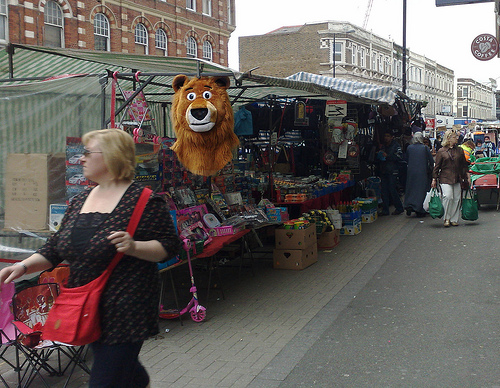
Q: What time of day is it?
A: Daytime.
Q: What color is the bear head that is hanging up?
A: Brown.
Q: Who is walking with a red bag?
A: A woman.